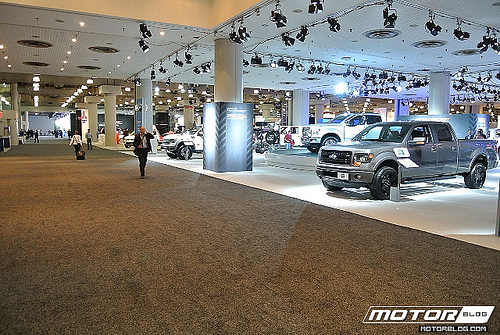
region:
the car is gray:
[308, 98, 493, 210]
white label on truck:
[379, 142, 445, 184]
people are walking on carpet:
[23, 113, 172, 190]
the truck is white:
[303, 84, 360, 141]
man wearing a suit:
[124, 121, 164, 172]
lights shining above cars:
[122, 8, 498, 105]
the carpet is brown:
[0, 129, 495, 326]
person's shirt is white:
[66, 126, 91, 150]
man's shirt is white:
[134, 129, 153, 152]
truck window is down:
[407, 114, 436, 150]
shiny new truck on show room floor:
[326, 112, 488, 214]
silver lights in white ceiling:
[129, 19, 155, 57]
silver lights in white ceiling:
[170, 50, 200, 80]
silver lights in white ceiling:
[230, 15, 252, 53]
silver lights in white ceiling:
[264, 3, 294, 36]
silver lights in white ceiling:
[251, 40, 275, 83]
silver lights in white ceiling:
[286, 20, 322, 55]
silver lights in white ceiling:
[324, 8, 342, 36]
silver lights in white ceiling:
[369, 5, 409, 28]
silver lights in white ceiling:
[426, 15, 445, 49]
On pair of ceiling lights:
[136, 22, 156, 41]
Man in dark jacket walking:
[130, 120, 155, 182]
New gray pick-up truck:
[312, 107, 497, 202]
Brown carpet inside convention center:
[66, 195, 231, 295]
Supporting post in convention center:
[210, 31, 250, 166]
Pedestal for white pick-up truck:
[257, 137, 397, 167]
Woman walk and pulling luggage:
[70, 125, 85, 161]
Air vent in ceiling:
[15, 32, 50, 49]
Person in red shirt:
[280, 130, 291, 150]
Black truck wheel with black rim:
[368, 167, 401, 199]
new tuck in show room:
[316, 113, 484, 198]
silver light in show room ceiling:
[136, 20, 162, 45]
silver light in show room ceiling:
[236, 22, 255, 44]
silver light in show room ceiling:
[256, 0, 289, 27]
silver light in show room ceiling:
[354, 14, 399, 31]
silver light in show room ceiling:
[411, 15, 443, 40]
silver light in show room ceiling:
[454, 19, 473, 53]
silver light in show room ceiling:
[266, 50, 302, 73]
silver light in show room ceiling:
[331, 59, 367, 86]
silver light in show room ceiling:
[391, 66, 436, 93]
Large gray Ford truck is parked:
[317, 113, 494, 200]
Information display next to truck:
[389, 144, 415, 201]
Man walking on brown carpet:
[135, 123, 155, 177]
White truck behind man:
[159, 123, 201, 163]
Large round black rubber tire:
[370, 163, 399, 202]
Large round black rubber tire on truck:
[372, 163, 397, 202]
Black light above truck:
[379, 6, 399, 29]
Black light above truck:
[326, 13, 341, 33]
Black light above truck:
[424, 15, 441, 37]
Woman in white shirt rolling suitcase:
[65, 128, 85, 160]